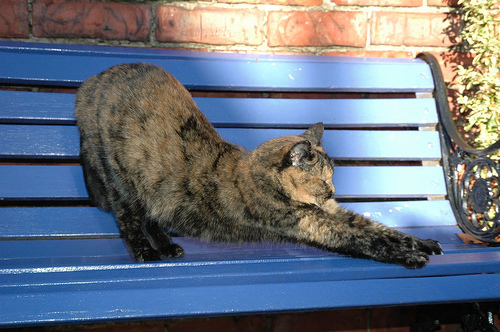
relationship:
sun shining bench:
[204, 2, 484, 243] [2, 37, 496, 322]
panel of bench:
[0, 50, 434, 91] [2, 37, 496, 322]